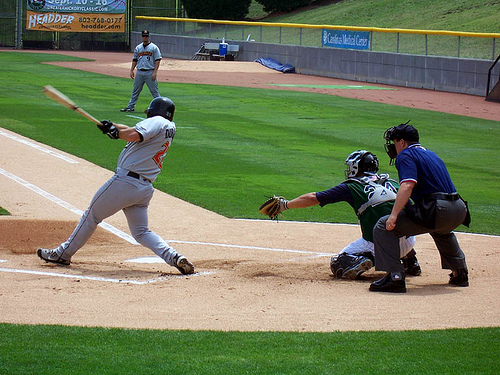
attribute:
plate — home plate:
[127, 254, 167, 264]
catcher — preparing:
[253, 149, 437, 281]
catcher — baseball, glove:
[252, 133, 427, 290]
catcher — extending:
[259, 148, 421, 278]